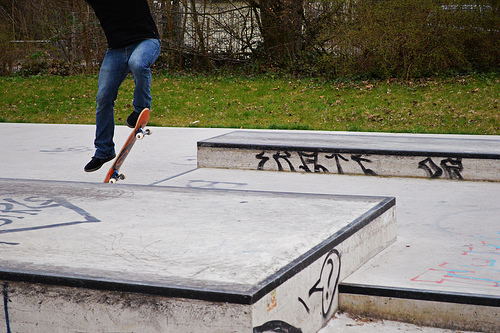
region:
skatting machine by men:
[84, 112, 164, 193]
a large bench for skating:
[206, 119, 499, 206]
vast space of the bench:
[9, 177, 358, 283]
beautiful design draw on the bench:
[303, 245, 356, 324]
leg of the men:
[76, 135, 126, 173]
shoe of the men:
[81, 151, 118, 171]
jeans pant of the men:
[90, 47, 175, 175]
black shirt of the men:
[100, 10, 172, 47]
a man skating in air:
[70, 1, 185, 167]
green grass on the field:
[211, 28, 492, 140]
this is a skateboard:
[105, 105, 162, 181]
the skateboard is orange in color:
[141, 110, 148, 124]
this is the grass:
[163, 96, 215, 120]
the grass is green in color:
[188, 81, 241, 126]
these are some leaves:
[316, 76, 446, 113]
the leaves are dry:
[342, 78, 422, 90]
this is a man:
[79, 4, 159, 171]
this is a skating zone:
[179, 181, 457, 257]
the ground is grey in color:
[173, 219, 235, 254]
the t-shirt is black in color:
[103, 7, 139, 29]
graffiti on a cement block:
[249, 146, 375, 180]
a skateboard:
[107, 112, 157, 188]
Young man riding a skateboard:
[72, 5, 190, 188]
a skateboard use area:
[6, 113, 472, 330]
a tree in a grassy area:
[233, 5, 335, 76]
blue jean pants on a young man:
[88, 42, 174, 169]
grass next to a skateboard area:
[200, 63, 498, 126]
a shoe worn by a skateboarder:
[77, 145, 114, 175]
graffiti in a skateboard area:
[305, 243, 353, 325]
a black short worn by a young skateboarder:
[88, 4, 166, 58]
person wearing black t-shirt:
[34, 6, 179, 191]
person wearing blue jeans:
[68, 24, 176, 183]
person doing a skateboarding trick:
[63, 74, 192, 205]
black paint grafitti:
[242, 108, 482, 203]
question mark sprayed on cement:
[293, 251, 379, 314]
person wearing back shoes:
[59, 14, 182, 231]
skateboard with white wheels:
[72, 86, 200, 234]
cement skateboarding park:
[23, 70, 475, 315]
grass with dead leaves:
[40, 36, 474, 140]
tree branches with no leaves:
[16, 7, 476, 75]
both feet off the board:
[63, 57, 197, 215]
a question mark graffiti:
[276, 222, 424, 322]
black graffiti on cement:
[220, 114, 490, 220]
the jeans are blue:
[52, 32, 337, 225]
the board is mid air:
[61, 27, 214, 195]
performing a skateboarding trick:
[61, 34, 196, 194]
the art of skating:
[61, 15, 257, 230]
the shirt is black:
[66, 17, 215, 233]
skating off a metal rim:
[48, 25, 383, 331]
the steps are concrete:
[42, 42, 347, 236]